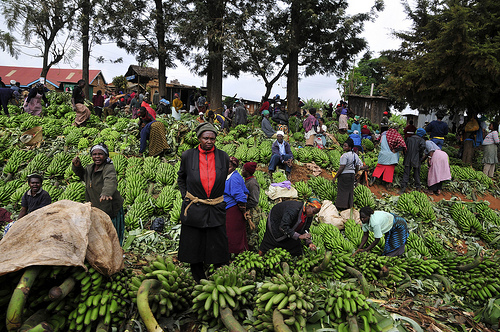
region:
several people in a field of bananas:
[1, 77, 446, 197]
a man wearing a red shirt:
[199, 145, 221, 186]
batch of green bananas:
[265, 282, 361, 316]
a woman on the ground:
[357, 206, 406, 256]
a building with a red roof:
[20, 65, 108, 85]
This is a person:
[354, 204, 423, 280]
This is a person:
[250, 192, 332, 277]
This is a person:
[334, 131, 364, 233]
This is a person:
[171, 115, 235, 290]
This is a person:
[64, 139, 135, 269]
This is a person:
[22, 162, 50, 242]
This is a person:
[267, 129, 297, 179]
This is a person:
[329, 127, 358, 218]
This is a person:
[400, 120, 429, 205]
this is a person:
[71, 138, 127, 255]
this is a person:
[352, 192, 407, 257]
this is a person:
[333, 133, 369, 208]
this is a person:
[368, 118, 405, 185]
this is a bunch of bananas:
[136, 257, 196, 326]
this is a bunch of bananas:
[252, 255, 307, 329]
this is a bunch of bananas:
[320, 259, 377, 329]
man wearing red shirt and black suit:
[178, 120, 232, 274]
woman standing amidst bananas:
[71, 143, 121, 241]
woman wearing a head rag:
[259, 196, 321, 253]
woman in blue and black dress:
[353, 205, 408, 256]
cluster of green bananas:
[448, 202, 481, 234]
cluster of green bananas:
[325, 281, 377, 330]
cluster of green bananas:
[127, 258, 196, 330]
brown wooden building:
[343, 92, 387, 126]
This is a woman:
[73, 140, 133, 252]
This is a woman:
[16, 167, 56, 235]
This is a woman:
[258, 182, 325, 273]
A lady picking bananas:
[347, 198, 417, 260]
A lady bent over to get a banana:
[261, 192, 325, 263]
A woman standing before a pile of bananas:
[177, 121, 232, 305]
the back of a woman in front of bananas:
[328, 131, 363, 213]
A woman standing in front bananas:
[67, 139, 134, 229]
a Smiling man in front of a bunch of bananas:
[19, 154, 56, 216]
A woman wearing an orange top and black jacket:
[178, 115, 231, 215]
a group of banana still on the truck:
[132, 265, 184, 325]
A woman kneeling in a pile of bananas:
[349, 200, 415, 262]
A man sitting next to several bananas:
[254, 128, 312, 170]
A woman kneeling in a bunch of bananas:
[349, 203, 419, 263]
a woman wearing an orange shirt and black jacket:
[177, 119, 234, 206]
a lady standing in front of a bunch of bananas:
[72, 134, 133, 214]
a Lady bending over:
[261, 196, 326, 250]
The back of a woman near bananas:
[332, 135, 371, 210]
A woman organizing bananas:
[347, 198, 418, 261]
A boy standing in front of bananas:
[21, 161, 51, 210]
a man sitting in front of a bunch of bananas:
[259, 128, 305, 172]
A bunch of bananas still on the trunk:
[194, 261, 256, 328]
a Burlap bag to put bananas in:
[4, 194, 127, 279]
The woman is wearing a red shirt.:
[191, 144, 218, 198]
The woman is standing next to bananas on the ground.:
[176, 125, 231, 265]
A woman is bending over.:
[263, 194, 323, 265]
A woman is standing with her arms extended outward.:
[65, 140, 127, 226]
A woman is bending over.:
[356, 203, 412, 252]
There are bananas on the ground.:
[12, 247, 499, 329]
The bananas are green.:
[2, 221, 499, 327]